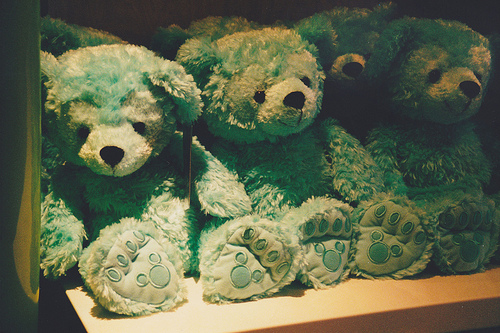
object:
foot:
[197, 213, 304, 307]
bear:
[172, 15, 441, 306]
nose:
[282, 91, 306, 110]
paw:
[198, 194, 254, 220]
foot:
[279, 195, 351, 289]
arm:
[38, 174, 89, 251]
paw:
[219, 227, 290, 288]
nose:
[99, 145, 125, 168]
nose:
[458, 81, 480, 98]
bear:
[39, 22, 301, 316]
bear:
[359, 20, 500, 275]